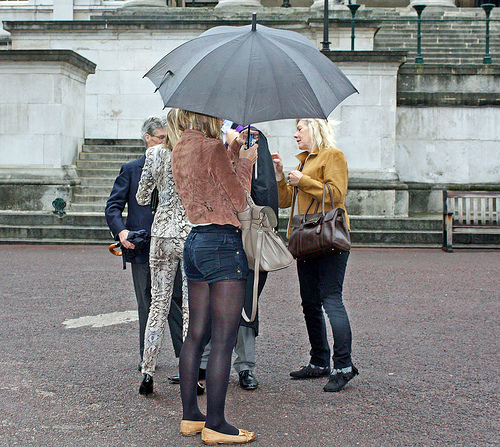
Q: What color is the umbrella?
A: Black.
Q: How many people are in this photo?
A: Five.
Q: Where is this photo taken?
A: On a street.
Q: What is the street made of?
A: Asphalt.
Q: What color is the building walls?
A: Gray.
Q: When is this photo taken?
A: Daytime.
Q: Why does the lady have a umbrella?
A: It's about to rain.